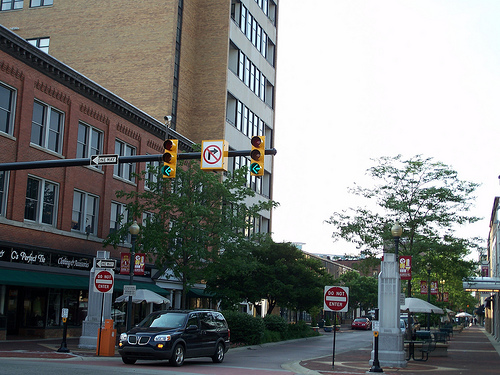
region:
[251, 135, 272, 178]
traffic light with a green arrow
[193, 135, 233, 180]
traffic sign showing no right turn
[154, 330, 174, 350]
headlight on a jeep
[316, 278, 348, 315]
do not enter traffic sign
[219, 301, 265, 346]
hedges on the side walk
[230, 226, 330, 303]
leaves on a tree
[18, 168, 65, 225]
glass on a window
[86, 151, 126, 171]
one way sign on a pole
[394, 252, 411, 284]
red flag on the pole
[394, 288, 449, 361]
umbrella on a table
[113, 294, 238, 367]
a car running on the road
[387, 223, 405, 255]
lamp with black color metal pole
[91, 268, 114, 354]
traffic sign board with metal pole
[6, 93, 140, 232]
window with the building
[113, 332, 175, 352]
headlight with indicator of the car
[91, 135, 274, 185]
traffic signals with metal pole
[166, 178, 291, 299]
trees with branches and leaves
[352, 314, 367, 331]
red color car parked in the parking area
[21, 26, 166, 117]
roof of the building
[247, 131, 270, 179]
a yellow traffic light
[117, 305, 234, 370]
a small van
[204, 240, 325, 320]
a large green tree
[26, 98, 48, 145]
a window of a building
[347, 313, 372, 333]
part of a red car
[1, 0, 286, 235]
part of a tall brown building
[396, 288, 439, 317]
part of a white umbrella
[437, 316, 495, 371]
part of a sidewalk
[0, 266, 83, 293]
part of a green canopy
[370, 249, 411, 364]
a tall statue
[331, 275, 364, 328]
There is a "Do Not Enter" sign here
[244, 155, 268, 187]
There is a green arrow visible here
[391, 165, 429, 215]
There is a green tree visible her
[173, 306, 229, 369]
There is a mini van visible here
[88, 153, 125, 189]
There is a "One Way" sign visible here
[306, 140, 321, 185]
There is a bright white sky here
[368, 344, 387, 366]
There is a green post here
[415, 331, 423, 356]
There is a picnic table here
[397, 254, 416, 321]
There is a red sign here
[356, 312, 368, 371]
There is a red car visible here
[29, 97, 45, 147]
glass window on building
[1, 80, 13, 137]
glass window on building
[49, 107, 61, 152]
glass window on building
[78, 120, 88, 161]
glass window on building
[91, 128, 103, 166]
glass window on building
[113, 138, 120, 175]
glass window on building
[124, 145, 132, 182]
glass window on building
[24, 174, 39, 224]
glass window on building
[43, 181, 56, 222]
glass window on building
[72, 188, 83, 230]
glass window on building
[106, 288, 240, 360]
black SUV driving by sign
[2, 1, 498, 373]
Commercial, town district, featuring dead end road.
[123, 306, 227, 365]
Black Suv, leaving dead end road.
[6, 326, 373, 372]
Perpendicular roads in town.